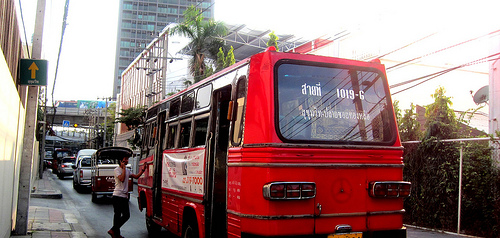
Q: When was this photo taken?
A: Daytime.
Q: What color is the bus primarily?
A: Red.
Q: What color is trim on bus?
A: Black.